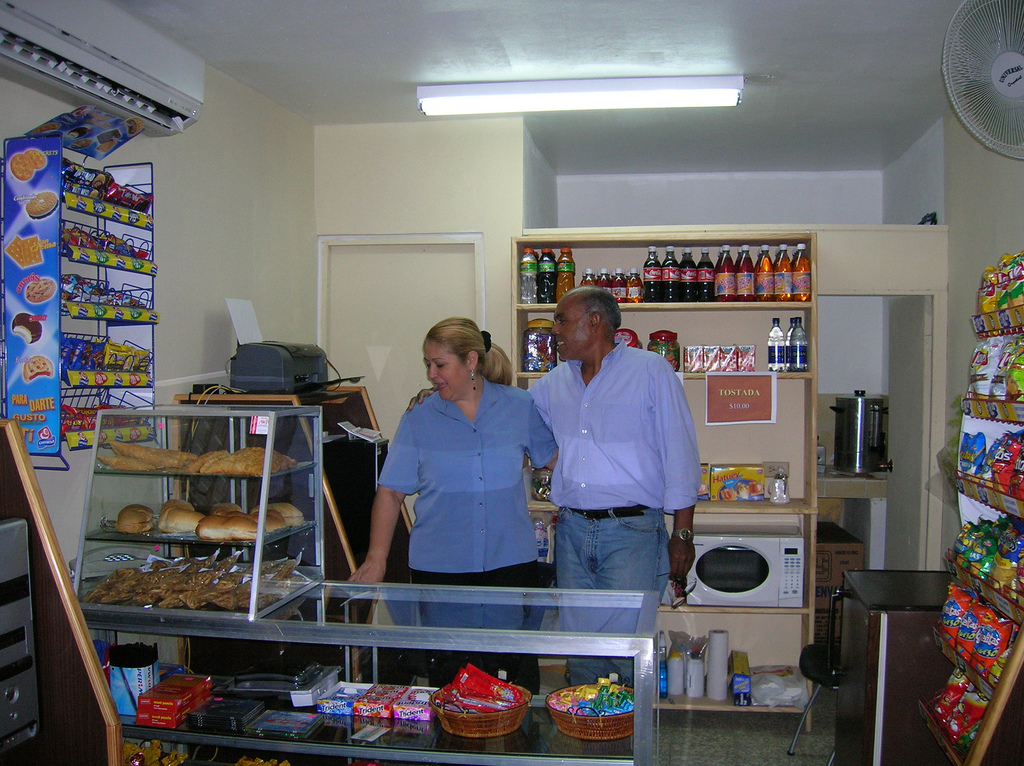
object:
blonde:
[433, 308, 512, 384]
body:
[417, 437, 519, 493]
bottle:
[761, 292, 781, 347]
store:
[0, 4, 989, 758]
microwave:
[670, 511, 830, 635]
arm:
[392, 368, 571, 443]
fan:
[940, 1, 1023, 165]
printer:
[217, 329, 333, 394]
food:
[79, 402, 318, 616]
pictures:
[5, 128, 60, 457]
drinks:
[513, 232, 842, 330]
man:
[347, 314, 557, 700]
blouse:
[371, 377, 572, 574]